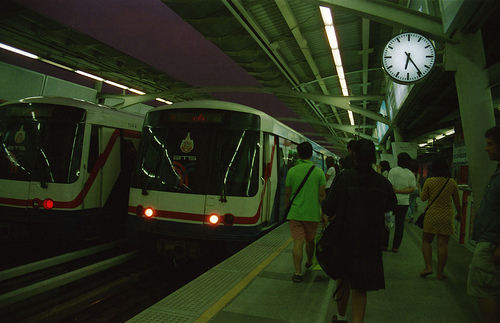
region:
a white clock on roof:
[373, 22, 444, 88]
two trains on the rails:
[5, 79, 336, 251]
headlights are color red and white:
[137, 200, 222, 228]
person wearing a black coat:
[311, 127, 403, 319]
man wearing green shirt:
[275, 134, 334, 287]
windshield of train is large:
[123, 106, 264, 201]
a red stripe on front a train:
[117, 186, 262, 231]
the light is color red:
[38, 190, 57, 211]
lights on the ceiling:
[311, 1, 371, 127]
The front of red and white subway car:
[120, 102, 270, 238]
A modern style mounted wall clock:
[373, 35, 445, 91]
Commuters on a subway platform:
[293, 112, 475, 312]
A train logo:
[168, 120, 205, 192]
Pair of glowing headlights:
[144, 204, 224, 233]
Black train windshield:
[138, 130, 255, 197]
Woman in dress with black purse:
[418, 161, 462, 285]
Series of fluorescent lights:
[319, 12, 358, 132]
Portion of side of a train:
[92, 130, 123, 203]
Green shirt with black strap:
[290, 162, 324, 230]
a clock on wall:
[378, 26, 440, 86]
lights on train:
[40, 193, 223, 230]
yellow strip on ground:
[184, 222, 293, 322]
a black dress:
[312, 165, 404, 295]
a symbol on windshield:
[13, 121, 195, 161]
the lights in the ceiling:
[313, 1, 360, 131]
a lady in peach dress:
[417, 156, 463, 284]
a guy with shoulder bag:
[281, 137, 328, 282]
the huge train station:
[1, 4, 498, 321]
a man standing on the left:
[461, 122, 498, 322]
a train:
[146, 109, 264, 225]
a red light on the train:
[205, 211, 225, 228]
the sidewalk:
[264, 279, 299, 309]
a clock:
[377, 35, 440, 81]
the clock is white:
[385, 30, 436, 82]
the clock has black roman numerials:
[382, 31, 436, 85]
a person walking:
[285, 144, 327, 278]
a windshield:
[141, 128, 251, 195]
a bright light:
[329, 37, 356, 74]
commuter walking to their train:
[285, 140, 322, 286]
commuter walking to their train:
[320, 137, 394, 321]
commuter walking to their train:
[417, 155, 463, 279]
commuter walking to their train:
[385, 150, 418, 252]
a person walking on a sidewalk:
[276, 136, 323, 278]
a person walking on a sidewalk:
[417, 151, 464, 274]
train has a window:
[136, 125, 161, 187]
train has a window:
[157, 125, 207, 194]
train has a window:
[209, 128, 256, 196]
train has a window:
[0, 116, 40, 178]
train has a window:
[119, 134, 139, 166]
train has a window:
[89, 125, 99, 172]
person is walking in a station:
[286, 140, 325, 279]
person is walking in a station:
[316, 139, 396, 321]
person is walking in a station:
[421, 158, 465, 278]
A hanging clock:
[365, 29, 441, 94]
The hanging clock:
[367, 25, 444, 87]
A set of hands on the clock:
[399, 45, 428, 77]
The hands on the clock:
[400, 47, 427, 78]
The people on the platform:
[287, 122, 498, 307]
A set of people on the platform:
[273, 112, 498, 313]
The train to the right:
[131, 90, 353, 257]